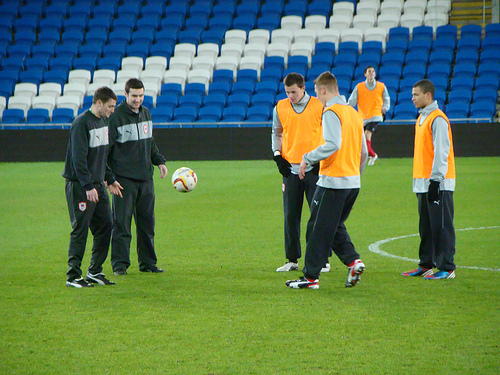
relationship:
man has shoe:
[402, 79, 459, 280] [425, 265, 458, 279]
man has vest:
[402, 79, 459, 280] [411, 107, 457, 179]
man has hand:
[104, 76, 169, 277] [159, 163, 169, 181]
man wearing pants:
[104, 76, 169, 277] [111, 171, 157, 269]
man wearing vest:
[270, 72, 332, 272] [273, 95, 327, 165]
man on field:
[104, 76, 169, 277] [1, 157, 499, 374]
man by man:
[104, 76, 169, 277] [62, 85, 125, 289]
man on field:
[270, 72, 332, 272] [1, 157, 499, 374]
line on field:
[366, 226, 499, 271] [1, 157, 499, 374]